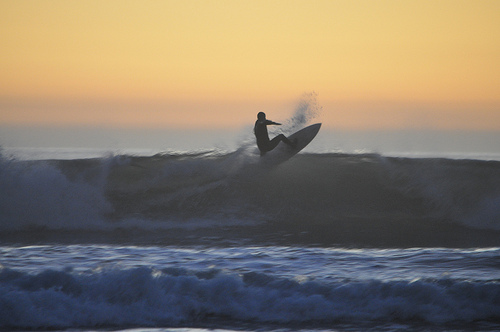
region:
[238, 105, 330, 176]
man on surfboard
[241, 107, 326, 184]
man catching a wave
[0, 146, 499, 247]
giant wave rolling in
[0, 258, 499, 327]
white foamy residue from wave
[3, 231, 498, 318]
remnants of wave rolling in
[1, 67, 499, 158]
view of sunset in horizon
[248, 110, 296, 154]
light casts shadow on man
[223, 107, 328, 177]
back of surfboard covered by wave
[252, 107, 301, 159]
man in dark wetsuit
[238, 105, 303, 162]
man's legs straddled on surfboard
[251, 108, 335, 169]
surfer in the water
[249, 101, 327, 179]
A man rides a wave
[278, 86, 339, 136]
The board kicking up water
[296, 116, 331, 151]
The tip of the surfboard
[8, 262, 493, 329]
The white water crashing down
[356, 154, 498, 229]
The wave breaking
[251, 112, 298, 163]
The surfer wears a wetsuit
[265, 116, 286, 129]
The mans arm is out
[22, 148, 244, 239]
The wave in the ocean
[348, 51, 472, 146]
The pink, blue and yellow sky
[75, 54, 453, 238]
the man is surfing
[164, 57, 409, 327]
the man is surfing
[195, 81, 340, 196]
surfer in the air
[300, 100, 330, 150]
surfboard below the man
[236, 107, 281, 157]
man on the board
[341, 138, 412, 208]
wave forming in the water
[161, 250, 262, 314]
water approaching the shore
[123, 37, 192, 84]
light sky above water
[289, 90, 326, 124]
water in the air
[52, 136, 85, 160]
still water in the background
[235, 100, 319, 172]
man surfing in the ocean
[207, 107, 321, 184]
man crouched on the surfboard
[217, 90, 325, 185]
surfer on board in ocean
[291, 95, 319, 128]
white water splashing from board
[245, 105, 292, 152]
surfer on board in ocean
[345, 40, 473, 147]
sunset along the horizon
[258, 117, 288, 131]
arms of surfer outstretched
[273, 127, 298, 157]
leg of surfer bent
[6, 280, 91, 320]
white wave splashing of water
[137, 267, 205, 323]
white wave splashing of water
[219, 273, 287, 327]
white wave splashing of water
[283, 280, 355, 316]
white wave splashing of water